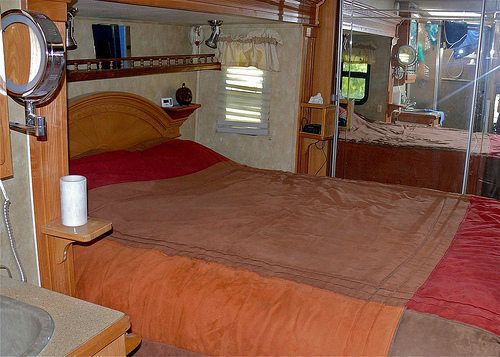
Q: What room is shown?
A: Bedroom.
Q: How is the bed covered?
A: With multi-color bedspread.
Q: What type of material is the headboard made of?
A: Wood.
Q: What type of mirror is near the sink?
A: Swing-arm mirror.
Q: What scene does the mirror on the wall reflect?
A: Bedroom scene.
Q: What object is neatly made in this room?
A: Bed.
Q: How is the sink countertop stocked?
A: Clear of toiletries.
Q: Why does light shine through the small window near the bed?
A: Daylight outside.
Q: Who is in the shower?
A: Shower empty.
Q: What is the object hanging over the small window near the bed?
A: Curtain.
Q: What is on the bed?
A: Blanket on the bed.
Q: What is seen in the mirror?
A: Reflection of the bed.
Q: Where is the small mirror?
A: Hanging on the wall.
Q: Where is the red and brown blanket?
A: On the bed.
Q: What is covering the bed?
A: Red and brown blanket.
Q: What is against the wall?
A: Wooden headboard.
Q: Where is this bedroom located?
A: In a camper.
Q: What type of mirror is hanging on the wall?
A: Round silver mirror.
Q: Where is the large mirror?
A: Next to the bed.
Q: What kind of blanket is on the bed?
A: Brown, red, and orange blanket.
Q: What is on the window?
A: Blinds.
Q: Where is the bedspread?
A: On the bed.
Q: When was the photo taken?
A: Daytime.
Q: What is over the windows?
A: Blinds.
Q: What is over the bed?
A: Spread.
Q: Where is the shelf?
A: Over the bed.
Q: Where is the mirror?
A: Wall.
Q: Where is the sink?
A: Beside the bed.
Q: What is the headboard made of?
A: Wood.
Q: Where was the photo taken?
A: In a bedroom.